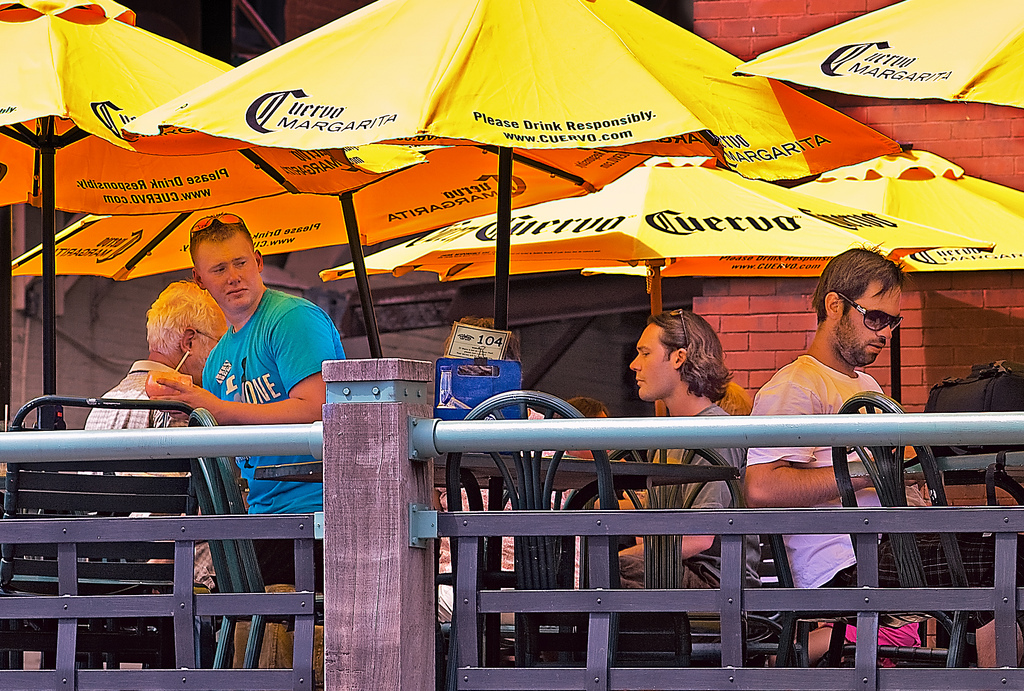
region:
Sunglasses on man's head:
[148, 215, 352, 621]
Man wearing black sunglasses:
[748, 246, 1023, 621]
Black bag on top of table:
[850, 363, 1019, 513]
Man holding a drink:
[148, 214, 365, 559]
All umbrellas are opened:
[12, 0, 1022, 431]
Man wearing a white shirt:
[746, 247, 1022, 614]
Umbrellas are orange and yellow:
[5, 0, 1021, 314]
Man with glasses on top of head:
[587, 306, 759, 611]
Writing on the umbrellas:
[0, 0, 1022, 327]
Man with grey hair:
[79, 282, 264, 578]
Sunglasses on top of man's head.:
[177, 205, 257, 238]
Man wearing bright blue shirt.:
[208, 328, 349, 512]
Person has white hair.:
[141, 279, 208, 349]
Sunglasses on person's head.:
[654, 294, 693, 359]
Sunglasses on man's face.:
[836, 287, 906, 345]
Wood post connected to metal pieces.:
[316, 386, 422, 685]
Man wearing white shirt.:
[754, 353, 903, 573]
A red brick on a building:
[720, 312, 779, 333]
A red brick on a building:
[750, 293, 808, 310]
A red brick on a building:
[925, 345, 954, 362]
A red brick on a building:
[989, 310, 1006, 329]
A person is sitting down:
[738, 222, 982, 614]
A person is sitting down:
[615, 311, 771, 574]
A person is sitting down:
[78, 266, 238, 435]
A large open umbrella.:
[132, 14, 921, 214]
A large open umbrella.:
[347, 152, 878, 305]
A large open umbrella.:
[716, 141, 1011, 282]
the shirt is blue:
[198, 290, 341, 515]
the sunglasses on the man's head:
[155, 214, 345, 608]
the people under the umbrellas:
[0, 0, 1021, 665]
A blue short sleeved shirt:
[174, 269, 367, 529]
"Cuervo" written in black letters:
[627, 181, 808, 254]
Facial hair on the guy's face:
[813, 291, 891, 371]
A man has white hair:
[117, 263, 248, 382]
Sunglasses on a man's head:
[171, 193, 282, 323]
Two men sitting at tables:
[596, 212, 1012, 655]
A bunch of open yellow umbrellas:
[1, 1, 1014, 305]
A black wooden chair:
[422, 367, 704, 668]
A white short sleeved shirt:
[734, 339, 930, 603]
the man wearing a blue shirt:
[144, 209, 347, 611]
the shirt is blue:
[200, 285, 344, 513]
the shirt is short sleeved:
[201, 285, 344, 511]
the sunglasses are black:
[827, 281, 901, 330]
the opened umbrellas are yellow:
[1, 2, 1022, 436]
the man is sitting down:
[734, 240, 1022, 667]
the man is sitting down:
[611, 312, 747, 614]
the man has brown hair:
[653, 310, 730, 402]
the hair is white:
[140, 277, 216, 361]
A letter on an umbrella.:
[647, 204, 693, 243]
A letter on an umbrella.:
[676, 215, 697, 236]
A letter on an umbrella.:
[717, 215, 740, 234]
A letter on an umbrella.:
[749, 212, 763, 226]